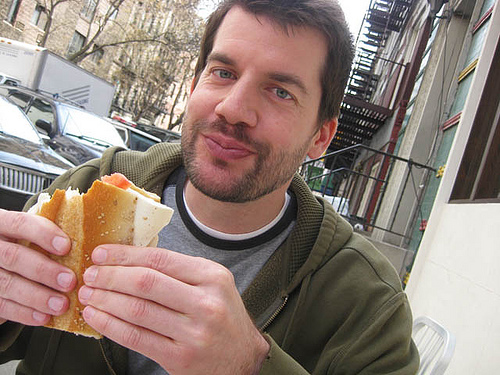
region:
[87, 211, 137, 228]
bread in man's hands.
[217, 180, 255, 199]
goatee on man's face.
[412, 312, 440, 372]
chair on the sidewalk.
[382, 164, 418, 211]
railing near the door.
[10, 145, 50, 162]
hood of the vehicle.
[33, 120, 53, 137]
mirror on the vehicle.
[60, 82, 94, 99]
logo on the truck.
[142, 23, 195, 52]
branches on the tree.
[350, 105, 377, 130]
platform of fire escape.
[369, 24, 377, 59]
stairs of fire escape.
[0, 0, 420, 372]
A man holding a sandwich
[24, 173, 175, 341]
A sandwich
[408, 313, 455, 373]
A silver colored metal chair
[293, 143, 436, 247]
some black metal handrails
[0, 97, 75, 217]
A parked black car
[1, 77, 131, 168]
A parked black car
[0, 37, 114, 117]
A large white truck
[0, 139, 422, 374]
A green jacket on a man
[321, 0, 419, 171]
A large fire escape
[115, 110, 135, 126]
A parked red car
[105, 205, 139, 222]
bread in man's hands.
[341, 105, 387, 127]
platform of the fire escape.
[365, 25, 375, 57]
stairs of the fire escape.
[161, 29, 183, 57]
leaves on the branches.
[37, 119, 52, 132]
side mirror on vehicle.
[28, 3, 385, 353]
man eating food with hands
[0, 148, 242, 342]
hands holding sandwich in them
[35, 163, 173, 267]
piece of brown and white bread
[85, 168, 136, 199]
pink meat inside sandwich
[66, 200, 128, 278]
sesame seeds on outside of sandwich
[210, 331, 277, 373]
brown hair on wrists of man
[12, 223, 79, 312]
finger nails on end of hands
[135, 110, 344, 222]
beard on face of man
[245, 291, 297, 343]
zipper on jacket on man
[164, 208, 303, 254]
two undershirts on man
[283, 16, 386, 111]
Man has short hair.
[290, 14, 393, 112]
Man has dark hair.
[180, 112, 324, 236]
Man has dark facial hair.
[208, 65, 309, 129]
Man has blue eyes.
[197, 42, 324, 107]
Man has dark eye brows.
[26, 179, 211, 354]
Man is holding sandwich.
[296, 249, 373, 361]
Man wearing green sweatshirt.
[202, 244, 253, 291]
Man wearing gray shirt.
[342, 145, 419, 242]
Black railing near building.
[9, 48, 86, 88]
White box truck in background.